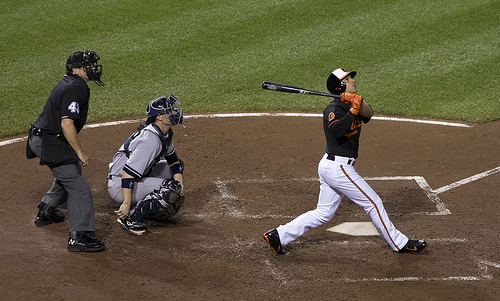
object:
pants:
[107, 157, 175, 202]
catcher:
[104, 94, 188, 237]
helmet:
[145, 94, 176, 117]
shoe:
[261, 227, 290, 257]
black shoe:
[65, 235, 109, 252]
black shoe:
[34, 207, 68, 226]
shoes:
[115, 210, 147, 237]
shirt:
[321, 93, 377, 158]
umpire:
[25, 50, 107, 254]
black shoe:
[395, 237, 429, 253]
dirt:
[0, 110, 500, 300]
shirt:
[105, 121, 179, 189]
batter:
[260, 67, 429, 256]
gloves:
[348, 92, 369, 116]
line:
[212, 174, 418, 185]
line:
[413, 174, 453, 216]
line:
[231, 208, 449, 219]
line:
[212, 177, 248, 219]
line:
[431, 163, 500, 195]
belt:
[321, 153, 359, 167]